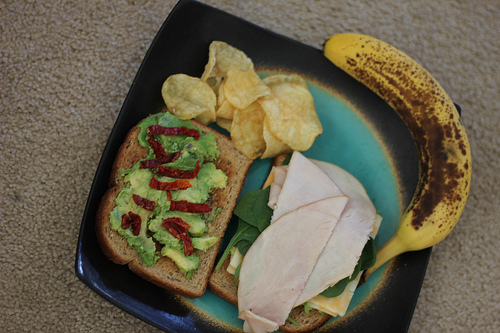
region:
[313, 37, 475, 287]
a banana almost ripe to eat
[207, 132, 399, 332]
slices of turkey meat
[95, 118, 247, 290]
slice of a bread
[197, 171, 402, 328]
slice of a bread with toppings on top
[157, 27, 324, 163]
potato chips on a plate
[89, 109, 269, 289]
lettuces on top of bread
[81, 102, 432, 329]
two slices of bread with toppings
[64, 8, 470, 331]
a curved square shape black plate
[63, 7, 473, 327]
plate with two slice of bread and a banana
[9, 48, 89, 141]
a beige carpet floor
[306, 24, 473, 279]
a ripped banana ready to eat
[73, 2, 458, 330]
a black rubber plate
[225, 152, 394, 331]
slices of turkey meat on bread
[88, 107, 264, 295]
a slice of bread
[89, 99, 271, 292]
lettuces on top of slice of bread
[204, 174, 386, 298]
spinach on top of bread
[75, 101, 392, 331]
two slices of bread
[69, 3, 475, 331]
a plate with two slice of bread and a banana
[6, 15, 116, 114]
a beige carpet floor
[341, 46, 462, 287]
yellow banana on plate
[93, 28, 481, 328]
black square dinner plate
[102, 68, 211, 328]
white bread on plate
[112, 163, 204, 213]
bacon bits on lettuce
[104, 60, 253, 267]
lettuce on wheat bread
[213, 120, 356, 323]
cut ham on sandwich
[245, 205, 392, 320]
yellow cheese on sandwich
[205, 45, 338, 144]
potato chips on plate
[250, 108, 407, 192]
teal circle on plate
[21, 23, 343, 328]
black plate on carpet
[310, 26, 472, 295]
a ripe banana on a plate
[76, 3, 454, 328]
a black and turquoise plate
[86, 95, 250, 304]
a bread slice with veggies and roasted tomatoes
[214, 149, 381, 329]
a bread slice with cheese, spring greens and sliced turkey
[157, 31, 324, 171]
chips on the plate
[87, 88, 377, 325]
a turkey sandwich with toppings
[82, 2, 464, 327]
sandwich lunch on a plate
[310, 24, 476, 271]
the banana is very ripe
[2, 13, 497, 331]
the plate is sitting on a carpet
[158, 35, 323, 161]
kettle cooked potato chips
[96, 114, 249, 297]
a piece of bread with guacamole and bacon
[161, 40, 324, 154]
thin and crispy potato chips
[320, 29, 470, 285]
an over ripened banana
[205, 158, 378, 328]
a piece of bread with meat cheese and lettuce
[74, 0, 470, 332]
a square plate with food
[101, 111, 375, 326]
an open faced sandwich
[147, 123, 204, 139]
a strip of bacon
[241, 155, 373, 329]
slices of lunch meat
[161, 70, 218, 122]
a potato chip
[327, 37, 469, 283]
a banana